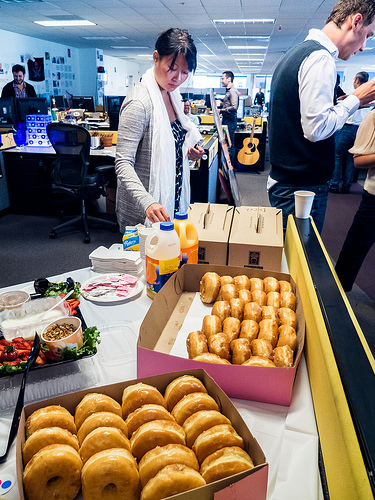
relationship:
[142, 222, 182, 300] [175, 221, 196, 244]
bottle of orange juice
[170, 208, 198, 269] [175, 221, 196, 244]
bottle of orange juice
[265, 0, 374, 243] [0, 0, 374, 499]
man inside office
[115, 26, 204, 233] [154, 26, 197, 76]
woman with hair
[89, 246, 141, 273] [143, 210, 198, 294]
napkins next to orange juice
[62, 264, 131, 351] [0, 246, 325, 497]
table has tablecloth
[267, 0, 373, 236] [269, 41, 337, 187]
man wearing dark vest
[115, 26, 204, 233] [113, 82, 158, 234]
woman in sweater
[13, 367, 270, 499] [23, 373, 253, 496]
box with donuts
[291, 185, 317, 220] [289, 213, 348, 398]
cup on rail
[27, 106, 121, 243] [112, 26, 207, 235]
desk chair behind woman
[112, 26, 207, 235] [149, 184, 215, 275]
woman looking at juice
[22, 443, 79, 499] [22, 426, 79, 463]
doughnut in a doughnut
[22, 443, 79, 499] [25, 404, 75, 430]
doughnut in a doughnut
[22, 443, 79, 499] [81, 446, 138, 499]
doughnut in a doughnut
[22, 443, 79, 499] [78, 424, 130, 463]
doughnut in a doughnut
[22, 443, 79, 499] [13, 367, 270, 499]
doughnut in a box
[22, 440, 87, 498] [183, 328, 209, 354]
doughnut in a doughnuts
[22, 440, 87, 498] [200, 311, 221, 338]
doughnut in a doughnuts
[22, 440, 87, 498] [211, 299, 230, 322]
doughnut in a doughnuts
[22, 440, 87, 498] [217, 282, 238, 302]
doughnut in a doughnuts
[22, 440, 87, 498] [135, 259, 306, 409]
doughnut in a box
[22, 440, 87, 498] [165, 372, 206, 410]
doughnut in a donuts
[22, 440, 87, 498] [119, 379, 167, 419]
doughnut in a donuts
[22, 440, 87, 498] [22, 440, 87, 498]
doughnut in a doughnut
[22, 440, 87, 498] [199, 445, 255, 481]
doughnut in a donuts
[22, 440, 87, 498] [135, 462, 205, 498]
doughnut in a donuts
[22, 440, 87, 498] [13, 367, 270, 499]
doughnut in a box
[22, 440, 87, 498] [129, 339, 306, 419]
doughnut in a box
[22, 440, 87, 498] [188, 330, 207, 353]
doughnut in a doughnuts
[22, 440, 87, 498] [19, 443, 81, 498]
doughnut in a doughnuts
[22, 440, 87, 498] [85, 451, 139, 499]
doughnut in a doughnuts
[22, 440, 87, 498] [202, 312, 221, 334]
doughnut in a doughnuts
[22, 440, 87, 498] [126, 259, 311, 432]
doughnut in a box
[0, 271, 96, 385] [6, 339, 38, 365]
black tray with strawberries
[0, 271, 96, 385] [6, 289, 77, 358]
black tray with food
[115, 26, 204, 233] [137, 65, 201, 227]
woman wearing scarf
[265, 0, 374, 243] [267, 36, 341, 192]
man wearing dark vest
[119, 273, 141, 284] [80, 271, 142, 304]
sugar packet on plate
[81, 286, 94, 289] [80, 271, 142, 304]
sugar packet on plate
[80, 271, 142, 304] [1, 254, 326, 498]
plate on table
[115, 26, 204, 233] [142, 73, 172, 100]
woman has neck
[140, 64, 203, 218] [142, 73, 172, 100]
scarf around neck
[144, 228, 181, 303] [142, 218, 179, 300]
juice in bottle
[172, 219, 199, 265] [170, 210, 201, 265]
juice in container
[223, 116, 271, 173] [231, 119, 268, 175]
guitar leaning against desk